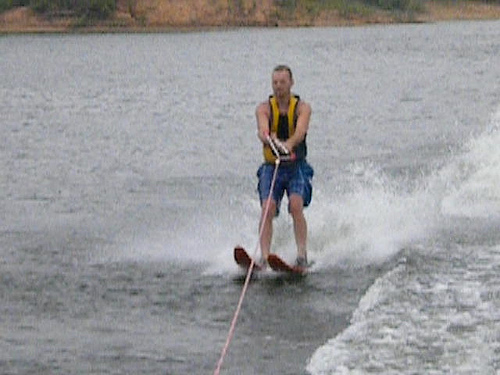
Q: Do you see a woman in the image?
A: No, there are no women.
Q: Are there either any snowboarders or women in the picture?
A: No, there are no women or snowboarders.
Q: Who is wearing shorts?
A: The man is wearing shorts.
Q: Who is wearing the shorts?
A: The man is wearing shorts.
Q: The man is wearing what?
A: The man is wearing shorts.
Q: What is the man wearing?
A: The man is wearing shorts.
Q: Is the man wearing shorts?
A: Yes, the man is wearing shorts.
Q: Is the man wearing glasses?
A: No, the man is wearing shorts.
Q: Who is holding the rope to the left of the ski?
A: The man is holding the rope.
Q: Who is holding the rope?
A: The man is holding the rope.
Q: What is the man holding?
A: The man is holding the rope.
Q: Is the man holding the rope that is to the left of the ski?
A: Yes, the man is holding the rope.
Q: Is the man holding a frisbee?
A: No, the man is holding the rope.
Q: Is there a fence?
A: No, there are no fences.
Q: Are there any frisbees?
A: No, there are no frisbees.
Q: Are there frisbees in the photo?
A: No, there are no frisbees.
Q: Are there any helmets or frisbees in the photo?
A: No, there are no frisbees or helmets.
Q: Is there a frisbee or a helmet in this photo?
A: No, there are no frisbees or helmets.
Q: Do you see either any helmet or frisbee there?
A: No, there are no frisbees or helmets.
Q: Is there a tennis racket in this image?
A: No, there are no rackets.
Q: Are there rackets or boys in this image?
A: No, there are no rackets or boys.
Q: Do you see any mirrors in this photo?
A: No, there are no mirrors.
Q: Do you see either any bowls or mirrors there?
A: No, there are no mirrors or bowls.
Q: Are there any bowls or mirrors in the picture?
A: No, there are no mirrors or bowls.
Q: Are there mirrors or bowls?
A: No, there are no mirrors or bowls.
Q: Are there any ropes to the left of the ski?
A: Yes, there is a rope to the left of the ski.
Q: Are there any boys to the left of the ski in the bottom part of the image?
A: No, there is a rope to the left of the ski.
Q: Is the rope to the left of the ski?
A: Yes, the rope is to the left of the ski.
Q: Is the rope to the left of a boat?
A: No, the rope is to the left of the ski.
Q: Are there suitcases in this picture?
A: No, there are no suitcases.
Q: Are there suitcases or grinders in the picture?
A: No, there are no suitcases or grinders.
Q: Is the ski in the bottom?
A: Yes, the ski is in the bottom of the image.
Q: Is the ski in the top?
A: No, the ski is in the bottom of the image.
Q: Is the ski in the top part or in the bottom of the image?
A: The ski is in the bottom of the image.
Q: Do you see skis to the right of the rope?
A: Yes, there is a ski to the right of the rope.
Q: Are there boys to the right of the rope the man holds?
A: No, there is a ski to the right of the rope.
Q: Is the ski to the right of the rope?
A: Yes, the ski is to the right of the rope.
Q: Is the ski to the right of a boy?
A: No, the ski is to the right of the rope.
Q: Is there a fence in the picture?
A: No, there are no fences.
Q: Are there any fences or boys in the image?
A: No, there are no fences or boys.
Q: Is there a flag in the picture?
A: No, there are no flags.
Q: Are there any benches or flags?
A: No, there are no flags or benches.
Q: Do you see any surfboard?
A: No, there are no surfboards.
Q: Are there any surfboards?
A: No, there are no surfboards.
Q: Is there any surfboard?
A: No, there are no surfboards.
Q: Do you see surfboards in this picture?
A: No, there are no surfboards.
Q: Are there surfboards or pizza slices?
A: No, there are no surfboards or pizza slices.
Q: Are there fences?
A: No, there are no fences.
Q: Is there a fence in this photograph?
A: No, there are no fences.